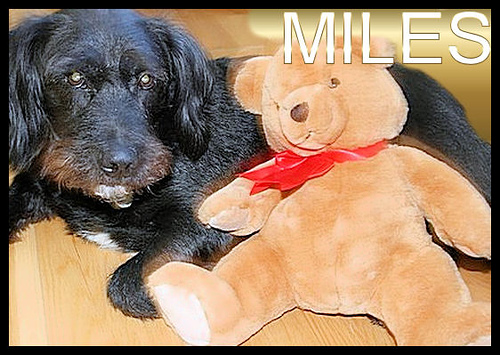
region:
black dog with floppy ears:
[8, 9, 489, 320]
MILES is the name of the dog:
[282, 10, 490, 65]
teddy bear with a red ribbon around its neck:
[142, 36, 489, 343]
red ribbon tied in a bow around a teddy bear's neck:
[233, 139, 388, 196]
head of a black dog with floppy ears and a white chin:
[10, 10, 215, 211]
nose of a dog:
[98, 144, 137, 179]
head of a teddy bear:
[232, 34, 410, 159]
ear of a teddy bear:
[232, 53, 274, 115]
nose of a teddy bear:
[288, 99, 310, 124]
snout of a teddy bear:
[276, 82, 347, 152]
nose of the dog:
[99, 130, 146, 197]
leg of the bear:
[163, 231, 288, 344]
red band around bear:
[266, 118, 376, 197]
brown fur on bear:
[306, 185, 389, 245]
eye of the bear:
[302, 65, 354, 117]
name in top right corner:
[271, 5, 491, 87]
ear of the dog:
[161, 23, 220, 145]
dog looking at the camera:
[8, 25, 235, 187]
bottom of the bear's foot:
[156, 280, 218, 346]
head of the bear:
[256, 47, 369, 154]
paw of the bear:
[193, 193, 270, 232]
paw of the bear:
[431, 201, 490, 265]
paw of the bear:
[138, 263, 245, 339]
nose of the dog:
[82, 152, 169, 197]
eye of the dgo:
[128, 68, 160, 97]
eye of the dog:
[61, 73, 88, 93]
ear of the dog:
[177, 110, 212, 153]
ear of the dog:
[1, 125, 41, 168]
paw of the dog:
[100, 274, 160, 317]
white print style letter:
[282, 9, 333, 64]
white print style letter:
[341, 12, 353, 63]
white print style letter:
[359, 11, 393, 63]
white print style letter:
[399, 6, 440, 66]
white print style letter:
[448, 13, 497, 67]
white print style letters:
[276, 10, 487, 70]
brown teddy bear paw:
[148, 268, 246, 340]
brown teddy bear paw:
[405, 305, 485, 345]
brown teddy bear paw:
[198, 189, 263, 237]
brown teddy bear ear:
[233, 55, 267, 117]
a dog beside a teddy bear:
[16, 14, 452, 310]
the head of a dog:
[31, 10, 177, 203]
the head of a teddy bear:
[229, 32, 411, 150]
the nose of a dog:
[96, 140, 140, 176]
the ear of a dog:
[153, 20, 232, 157]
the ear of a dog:
[3, 22, 55, 166]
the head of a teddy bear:
[236, 34, 413, 152]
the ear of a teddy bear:
[223, 50, 264, 118]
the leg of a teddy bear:
[136, 247, 276, 339]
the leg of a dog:
[98, 240, 213, 315]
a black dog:
[34, 29, 219, 246]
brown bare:
[211, 65, 421, 327]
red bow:
[234, 100, 367, 238]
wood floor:
[46, 212, 182, 354]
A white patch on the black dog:
[31, 151, 193, 290]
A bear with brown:
[253, 63, 365, 185]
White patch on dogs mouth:
[71, 169, 168, 221]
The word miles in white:
[256, 14, 481, 107]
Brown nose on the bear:
[274, 86, 342, 133]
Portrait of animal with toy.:
[4, 6, 489, 341]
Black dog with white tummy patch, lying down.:
[19, 13, 489, 310]